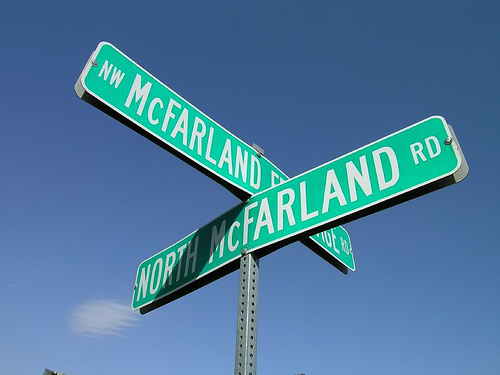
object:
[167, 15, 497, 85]
sky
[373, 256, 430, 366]
sky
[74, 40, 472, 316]
signs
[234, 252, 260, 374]
bar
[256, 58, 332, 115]
clouds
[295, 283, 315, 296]
clouds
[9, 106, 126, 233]
sky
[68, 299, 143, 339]
cloud